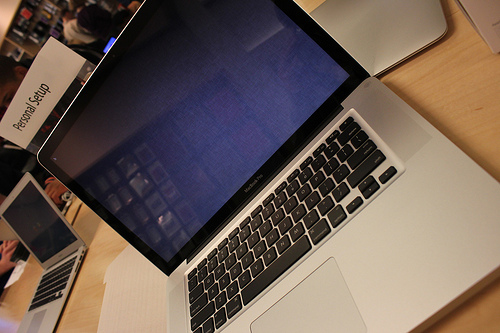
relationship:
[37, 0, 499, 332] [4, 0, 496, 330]
apple-macbook pro on surface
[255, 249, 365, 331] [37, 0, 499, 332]
pad on apple-macbook pro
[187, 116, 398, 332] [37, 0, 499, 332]
black keyboard on apple-macbook pro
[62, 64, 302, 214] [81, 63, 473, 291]
screen of laptop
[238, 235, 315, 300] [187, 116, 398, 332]
space bar of black keyboard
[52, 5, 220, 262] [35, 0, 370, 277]
reflection on screen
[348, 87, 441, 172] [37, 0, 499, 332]
grill of apple-macbook pro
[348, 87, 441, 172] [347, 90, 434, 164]
grill of speaker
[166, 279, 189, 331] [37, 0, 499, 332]
speaker grill of apple-macbook pro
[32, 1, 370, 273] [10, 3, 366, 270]
frame on screen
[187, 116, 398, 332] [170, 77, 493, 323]
black keyboard on in case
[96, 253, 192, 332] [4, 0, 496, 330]
paper on surface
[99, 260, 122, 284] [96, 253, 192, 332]
corner of paper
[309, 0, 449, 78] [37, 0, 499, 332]
case behind apple-macbook pro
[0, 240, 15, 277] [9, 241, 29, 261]
hand on object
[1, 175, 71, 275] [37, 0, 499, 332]
hands on apple-macbook pro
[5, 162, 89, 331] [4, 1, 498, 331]
laptop on table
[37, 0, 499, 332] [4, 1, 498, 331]
apple-macbook pro on table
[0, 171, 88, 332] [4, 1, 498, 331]
laptop on table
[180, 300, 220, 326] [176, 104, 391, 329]
key on keyboard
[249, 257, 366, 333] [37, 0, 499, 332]
pad on apple-macbook pro